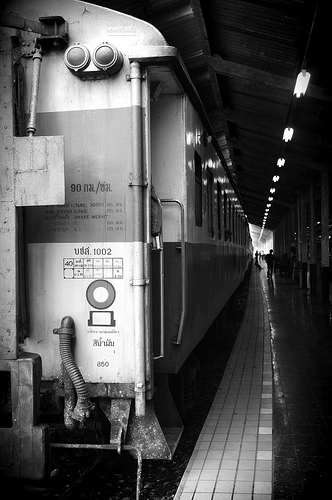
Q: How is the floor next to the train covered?
A: In tiles.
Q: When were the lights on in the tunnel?
A: While the train was stopped.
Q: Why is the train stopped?
A: Because it is in the station.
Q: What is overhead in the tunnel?
A: Lights.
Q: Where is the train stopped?
A: In the station.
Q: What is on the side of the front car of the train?
A: Holding bars and a step.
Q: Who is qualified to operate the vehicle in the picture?
A: A conductor.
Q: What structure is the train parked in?
A: A tunnel.